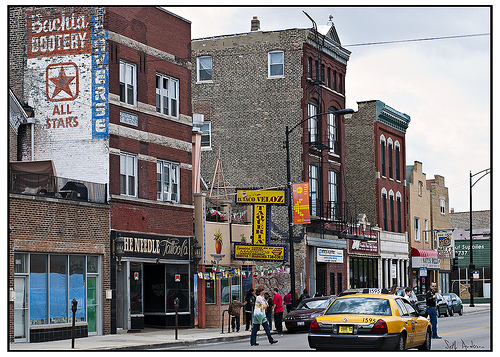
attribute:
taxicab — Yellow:
[310, 279, 432, 347]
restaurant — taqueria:
[124, 226, 189, 257]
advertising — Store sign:
[125, 228, 193, 256]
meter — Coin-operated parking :
[66, 290, 79, 343]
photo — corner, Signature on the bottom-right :
[12, 11, 483, 348]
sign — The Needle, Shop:
[124, 236, 162, 254]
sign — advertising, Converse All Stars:
[21, 11, 112, 182]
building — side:
[11, 10, 202, 330]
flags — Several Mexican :
[287, 176, 315, 224]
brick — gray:
[194, 41, 308, 293]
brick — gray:
[203, 27, 343, 292]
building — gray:
[200, 27, 349, 321]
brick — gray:
[196, 17, 345, 325]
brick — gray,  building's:
[282, 100, 300, 112]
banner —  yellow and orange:
[284, 184, 307, 225]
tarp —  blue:
[28, 273, 91, 318]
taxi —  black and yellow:
[304, 291, 433, 351]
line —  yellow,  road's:
[439, 317, 488, 338]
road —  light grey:
[424, 304, 491, 349]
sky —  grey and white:
[339, 6, 491, 169]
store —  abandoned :
[10, 199, 111, 340]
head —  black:
[70, 299, 79, 315]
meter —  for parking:
[70, 297, 79, 353]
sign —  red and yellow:
[290, 182, 313, 227]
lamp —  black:
[282, 108, 351, 304]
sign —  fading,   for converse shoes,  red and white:
[28, 13, 111, 140]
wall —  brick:
[11, 2, 32, 162]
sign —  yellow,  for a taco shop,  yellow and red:
[228, 188, 284, 262]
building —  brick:
[302, 8, 351, 302]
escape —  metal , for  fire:
[315, 31, 325, 161]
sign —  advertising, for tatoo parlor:
[110, 235, 200, 260]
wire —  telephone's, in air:
[340, 30, 496, 50]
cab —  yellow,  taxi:
[304, 288, 436, 351]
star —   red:
[48, 62, 75, 100]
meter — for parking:
[173, 295, 185, 342]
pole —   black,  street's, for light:
[280, 106, 350, 300]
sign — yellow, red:
[223, 177, 283, 261]